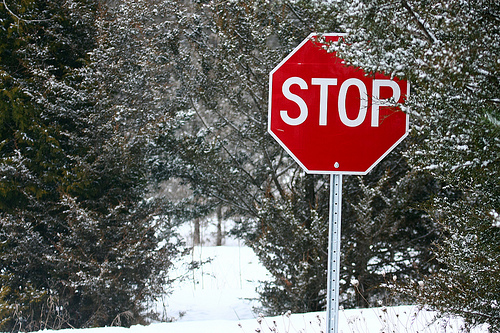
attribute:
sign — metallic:
[264, 5, 416, 313]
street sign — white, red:
[269, 32, 411, 173]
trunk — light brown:
[187, 206, 243, 256]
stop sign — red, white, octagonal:
[267, 29, 426, 172]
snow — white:
[40, 12, 222, 324]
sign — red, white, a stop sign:
[222, 57, 447, 224]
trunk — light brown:
[214, 199, 224, 249]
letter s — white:
[278, 77, 309, 127]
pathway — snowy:
[158, 237, 253, 327]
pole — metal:
[325, 171, 339, 330]